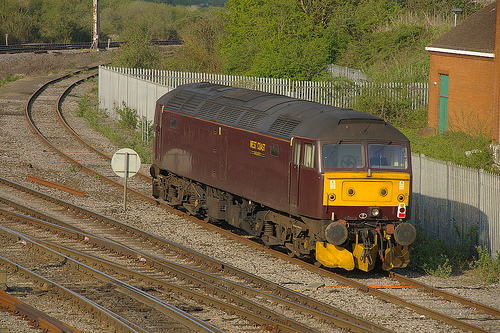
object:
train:
[322, 141, 412, 215]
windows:
[324, 141, 407, 173]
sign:
[106, 147, 141, 177]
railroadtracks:
[24, 91, 82, 126]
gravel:
[39, 108, 71, 153]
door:
[437, 73, 449, 139]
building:
[423, 2, 500, 142]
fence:
[250, 77, 427, 107]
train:
[151, 84, 419, 275]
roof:
[432, 0, 500, 49]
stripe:
[370, 285, 416, 289]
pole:
[26, 170, 91, 201]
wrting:
[249, 139, 266, 158]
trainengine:
[330, 173, 418, 213]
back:
[110, 147, 142, 213]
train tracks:
[23, 94, 79, 260]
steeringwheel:
[340, 155, 357, 168]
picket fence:
[99, 66, 151, 122]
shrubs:
[168, 17, 222, 70]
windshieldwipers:
[327, 140, 343, 161]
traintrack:
[19, 79, 90, 149]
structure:
[421, 2, 499, 142]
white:
[260, 79, 366, 91]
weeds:
[105, 101, 138, 132]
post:
[98, 147, 142, 215]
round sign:
[110, 147, 142, 178]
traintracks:
[23, 103, 110, 218]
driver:
[371, 148, 390, 166]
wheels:
[236, 214, 279, 243]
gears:
[186, 187, 206, 208]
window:
[440, 74, 447, 91]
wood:
[308, 275, 328, 294]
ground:
[218, 245, 271, 270]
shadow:
[406, 194, 492, 279]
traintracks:
[13, 261, 332, 302]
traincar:
[157, 89, 250, 181]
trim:
[310, 241, 365, 266]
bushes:
[215, 38, 328, 66]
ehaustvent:
[165, 90, 209, 115]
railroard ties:
[180, 293, 198, 309]